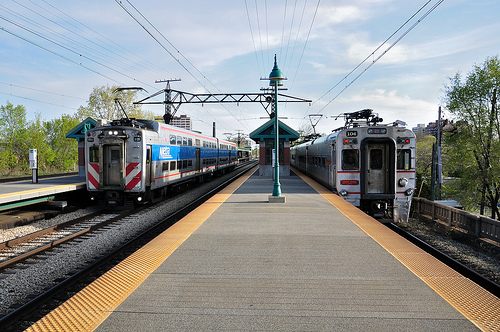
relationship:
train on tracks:
[82, 135, 159, 209] [29, 191, 125, 262]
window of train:
[90, 149, 105, 162] [82, 135, 159, 209]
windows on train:
[150, 128, 217, 145] [82, 135, 159, 209]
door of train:
[105, 147, 138, 184] [82, 135, 159, 209]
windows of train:
[150, 128, 217, 145] [82, 135, 159, 209]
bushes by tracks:
[453, 129, 480, 195] [29, 191, 125, 262]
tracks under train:
[29, 191, 125, 262] [82, 135, 159, 209]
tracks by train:
[29, 191, 125, 262] [82, 135, 159, 209]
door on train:
[105, 147, 138, 184] [82, 135, 159, 209]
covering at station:
[250, 118, 279, 145] [178, 90, 493, 253]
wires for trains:
[89, 8, 393, 59] [80, 78, 406, 202]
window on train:
[90, 149, 105, 162] [82, 135, 159, 209]